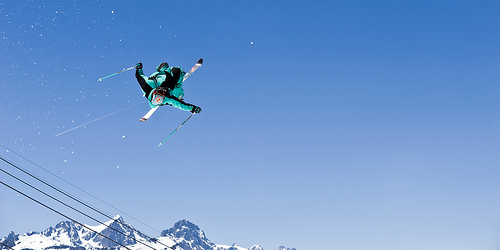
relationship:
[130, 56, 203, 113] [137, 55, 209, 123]
person on skis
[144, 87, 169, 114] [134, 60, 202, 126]
helmet of skier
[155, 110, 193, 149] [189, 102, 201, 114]
pole in hand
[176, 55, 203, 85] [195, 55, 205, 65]
ski with black tip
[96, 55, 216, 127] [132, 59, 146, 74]
pole in hand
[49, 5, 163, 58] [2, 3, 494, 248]
snow scattered in sky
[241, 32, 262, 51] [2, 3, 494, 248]
snow scattered in sky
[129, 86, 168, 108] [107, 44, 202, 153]
helmet on man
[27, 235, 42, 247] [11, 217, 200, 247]
snow on mountain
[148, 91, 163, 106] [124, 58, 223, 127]
hat on skier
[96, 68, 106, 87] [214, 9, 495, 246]
flecks in sky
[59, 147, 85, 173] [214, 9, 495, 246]
flecks in sky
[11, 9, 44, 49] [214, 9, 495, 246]
flecks in sky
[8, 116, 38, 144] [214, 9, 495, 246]
flecks in sky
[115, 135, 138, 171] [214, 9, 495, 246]
flecks in sky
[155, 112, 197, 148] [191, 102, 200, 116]
pole in hand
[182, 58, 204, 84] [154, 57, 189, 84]
ski on feet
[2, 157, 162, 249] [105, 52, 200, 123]
power lines beneath skier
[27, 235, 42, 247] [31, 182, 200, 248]
snow covering mountains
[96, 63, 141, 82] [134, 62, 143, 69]
pole on hand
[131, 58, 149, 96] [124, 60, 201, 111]
arm of a man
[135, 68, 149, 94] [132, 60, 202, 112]
arm of a man